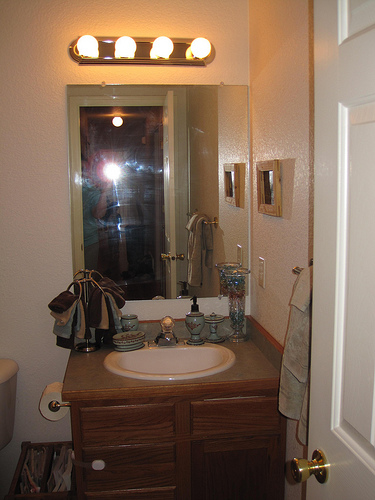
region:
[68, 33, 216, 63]
light fixture over sink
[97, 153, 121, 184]
reflection of camera flash in mirror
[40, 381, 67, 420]
roll of toilet paper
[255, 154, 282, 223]
wood-framed artwork on wall on right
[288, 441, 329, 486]
gold-colored doorknob on white door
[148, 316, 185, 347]
silver faucet for sink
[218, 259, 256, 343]
tall glass vase on right of sink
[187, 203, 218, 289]
reflection in mirror of towel hanging near door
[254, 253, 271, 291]
electrical outlet on wall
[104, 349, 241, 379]
white sink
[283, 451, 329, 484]
the knob is gold and shiney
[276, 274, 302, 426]
the towels are hanging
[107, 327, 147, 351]
the soap dish is empty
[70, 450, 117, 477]
the cabinets are child proof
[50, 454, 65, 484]
the magazines are beside the toliet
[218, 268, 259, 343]
the vase is tall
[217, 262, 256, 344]
the vase is made of glass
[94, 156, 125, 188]
the flash is showing in the mirror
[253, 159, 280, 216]
the picture is hanging from the wall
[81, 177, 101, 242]
the shirt is green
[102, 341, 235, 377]
the white sink basin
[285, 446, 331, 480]
the golden door knob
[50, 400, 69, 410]
the golden toilet paper roll holder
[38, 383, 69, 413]
whte toilet paper roll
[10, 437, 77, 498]
a full magazine rack on the floor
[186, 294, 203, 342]
a ceramic soap dispensor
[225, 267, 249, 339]
a cut glass multi colored vase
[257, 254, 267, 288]
a white electrical outlet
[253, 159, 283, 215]
a wooden framed picture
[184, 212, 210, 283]
a towel hanging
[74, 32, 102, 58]
a circle light bulb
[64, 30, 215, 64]
a small light fixture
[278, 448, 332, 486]
a gold door knob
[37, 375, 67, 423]
a white roll of tissue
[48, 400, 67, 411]
part of a tissue holder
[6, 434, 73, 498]
a wooden book crate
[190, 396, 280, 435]
a wooden drawer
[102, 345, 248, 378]
a white circle sink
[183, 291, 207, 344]
a tall soap dish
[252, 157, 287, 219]
a small picture frame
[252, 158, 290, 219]
a small brown picture frame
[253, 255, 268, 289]
a small electrical outlet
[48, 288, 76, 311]
a brown towel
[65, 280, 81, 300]
a silver towel hanger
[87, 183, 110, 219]
the arm of a person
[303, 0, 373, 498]
a white door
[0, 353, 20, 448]
part of a toilet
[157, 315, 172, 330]
a clear faucet handle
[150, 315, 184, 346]
a silver sink faucet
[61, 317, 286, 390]
a sink counter top